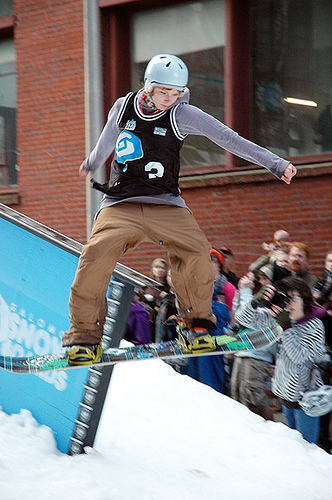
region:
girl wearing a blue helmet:
[142, 55, 191, 99]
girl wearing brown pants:
[72, 195, 219, 331]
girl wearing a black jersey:
[113, 93, 183, 197]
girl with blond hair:
[138, 79, 156, 105]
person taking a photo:
[256, 283, 315, 328]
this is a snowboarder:
[3, 50, 312, 403]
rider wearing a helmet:
[129, 47, 196, 99]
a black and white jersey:
[92, 86, 191, 220]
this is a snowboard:
[0, 302, 291, 408]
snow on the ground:
[53, 277, 329, 488]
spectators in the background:
[135, 208, 329, 436]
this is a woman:
[231, 264, 325, 438]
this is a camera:
[258, 269, 292, 320]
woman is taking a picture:
[237, 261, 329, 445]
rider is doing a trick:
[21, 13, 324, 464]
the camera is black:
[267, 276, 292, 310]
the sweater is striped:
[271, 325, 326, 400]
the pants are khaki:
[60, 215, 221, 328]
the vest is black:
[115, 90, 178, 194]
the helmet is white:
[151, 55, 187, 88]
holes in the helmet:
[158, 55, 182, 71]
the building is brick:
[194, 181, 325, 256]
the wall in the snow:
[0, 253, 138, 461]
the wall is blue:
[0, 270, 93, 438]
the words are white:
[1, 305, 70, 392]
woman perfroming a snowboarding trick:
[5, 42, 290, 364]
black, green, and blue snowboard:
[4, 320, 292, 387]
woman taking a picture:
[238, 280, 324, 438]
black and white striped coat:
[233, 297, 323, 403]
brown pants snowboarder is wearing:
[73, 204, 223, 334]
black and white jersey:
[106, 90, 182, 194]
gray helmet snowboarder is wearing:
[141, 50, 190, 94]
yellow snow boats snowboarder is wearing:
[64, 328, 216, 369]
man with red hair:
[284, 245, 316, 288]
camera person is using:
[268, 287, 284, 309]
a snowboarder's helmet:
[142, 53, 189, 94]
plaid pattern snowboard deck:
[0, 323, 285, 373]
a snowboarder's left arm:
[179, 105, 298, 185]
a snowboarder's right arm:
[80, 89, 130, 177]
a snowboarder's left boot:
[176, 327, 216, 355]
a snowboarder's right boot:
[64, 343, 99, 367]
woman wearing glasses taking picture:
[234, 276, 329, 441]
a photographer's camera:
[267, 289, 289, 308]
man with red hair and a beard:
[290, 242, 311, 274]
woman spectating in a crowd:
[149, 256, 167, 280]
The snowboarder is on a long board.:
[1, 325, 304, 373]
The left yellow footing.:
[66, 339, 107, 368]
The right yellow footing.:
[173, 322, 219, 354]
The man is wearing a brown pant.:
[67, 204, 211, 329]